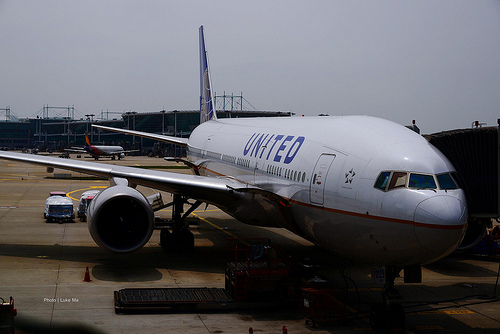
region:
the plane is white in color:
[205, 109, 424, 295]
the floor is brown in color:
[23, 254, 71, 326]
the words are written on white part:
[220, 106, 312, 163]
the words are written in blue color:
[233, 122, 297, 180]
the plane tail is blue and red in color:
[78, 136, 102, 158]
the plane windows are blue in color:
[414, 171, 467, 191]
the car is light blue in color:
[33, 188, 96, 259]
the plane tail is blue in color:
[194, 25, 214, 116]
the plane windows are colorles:
[204, 152, 273, 198]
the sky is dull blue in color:
[311, 32, 379, 70]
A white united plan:
[180, 107, 436, 259]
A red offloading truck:
[197, 232, 291, 294]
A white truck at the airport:
[38, 188, 75, 230]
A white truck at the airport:
[72, 186, 97, 223]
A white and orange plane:
[61, 124, 125, 159]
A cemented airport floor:
[22, 266, 102, 330]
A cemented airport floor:
[118, 309, 246, 326]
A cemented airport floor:
[8, 206, 68, 239]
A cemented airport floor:
[12, 162, 63, 194]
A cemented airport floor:
[432, 266, 469, 330]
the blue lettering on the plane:
[228, 127, 308, 164]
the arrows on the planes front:
[342, 166, 358, 186]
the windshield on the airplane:
[371, 163, 469, 201]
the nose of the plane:
[421, 196, 469, 247]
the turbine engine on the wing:
[85, 170, 152, 257]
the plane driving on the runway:
[69, 121, 131, 163]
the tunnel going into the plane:
[454, 126, 498, 216]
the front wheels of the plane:
[371, 296, 408, 331]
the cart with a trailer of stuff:
[41, 183, 78, 225]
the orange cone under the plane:
[71, 260, 98, 287]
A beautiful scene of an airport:
[2, 10, 492, 320]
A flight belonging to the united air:
[0, 15, 475, 280]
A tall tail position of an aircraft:
[3, 19, 485, 310]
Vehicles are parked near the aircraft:
[46, 190, 111, 240]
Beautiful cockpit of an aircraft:
[10, 15, 473, 288]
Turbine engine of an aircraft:
[6, 139, 287, 313]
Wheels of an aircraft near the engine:
[2, 8, 480, 319]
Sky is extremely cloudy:
[3, 5, 495, 122]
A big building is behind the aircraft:
[3, 8, 468, 331]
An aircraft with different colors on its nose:
[79, 123, 143, 167]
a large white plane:
[27, 78, 476, 265]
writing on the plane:
[244, 130, 306, 170]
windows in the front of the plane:
[384, 168, 459, 188]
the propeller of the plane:
[84, 188, 164, 251]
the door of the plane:
[307, 153, 330, 202]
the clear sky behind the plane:
[238, 21, 458, 91]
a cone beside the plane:
[74, 265, 98, 283]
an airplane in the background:
[71, 130, 141, 164]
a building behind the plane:
[10, 95, 245, 166]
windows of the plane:
[197, 146, 272, 173]